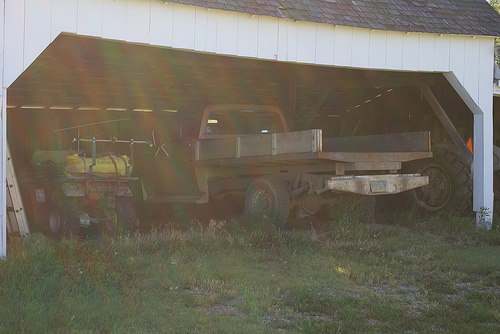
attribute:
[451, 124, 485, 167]
triangle — orange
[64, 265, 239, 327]
grass — green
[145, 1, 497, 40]
roof — black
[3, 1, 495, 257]
carport — white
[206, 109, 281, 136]
window — back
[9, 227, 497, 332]
grass — brown, blades, tall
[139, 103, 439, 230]
truck — old, pickup, red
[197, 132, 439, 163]
bed — brown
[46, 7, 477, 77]
planks — brown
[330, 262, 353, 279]
patch — yellow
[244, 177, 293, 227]
tire — round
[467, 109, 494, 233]
post — white, wooden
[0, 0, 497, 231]
barn — white, wooden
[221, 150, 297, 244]
tire — black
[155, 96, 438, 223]
vehicle — all terrin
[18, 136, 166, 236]
vehicle — all terrin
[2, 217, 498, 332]
grass — green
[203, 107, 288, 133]
window — rear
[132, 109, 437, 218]
truck — pickup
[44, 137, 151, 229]
tool — green, yellow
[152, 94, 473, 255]
truck — parked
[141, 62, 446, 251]
truck — old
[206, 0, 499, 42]
roof — black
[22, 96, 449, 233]
vehicles — parked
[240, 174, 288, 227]
tire — black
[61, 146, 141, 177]
container — yellow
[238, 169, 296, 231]
tire — dirty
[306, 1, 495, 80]
roof — Grey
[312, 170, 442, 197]
bumper — rusty